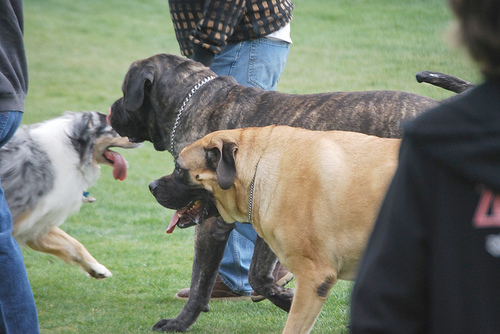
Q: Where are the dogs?
A: At the park.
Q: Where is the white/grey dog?
A: Left Side.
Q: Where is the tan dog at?
A: Right side.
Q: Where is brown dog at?
A: Between other dogs.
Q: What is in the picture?
A: Three dogs.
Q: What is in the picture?
A: Three people.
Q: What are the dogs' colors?
A: Brown, black, white and gray.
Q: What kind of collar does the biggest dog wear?
A: Silver chain collar.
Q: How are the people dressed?
A: For chilly weather.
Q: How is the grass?
A: Well manicured and green.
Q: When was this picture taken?
A: Maybe the afternoon.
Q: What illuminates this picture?
A: Natural sunlight.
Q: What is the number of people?
A: Three.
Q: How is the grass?
A: Well manicured green lawn.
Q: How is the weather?
A: Sunny.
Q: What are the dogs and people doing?
A: Walking and playing.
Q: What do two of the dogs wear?
A: Silver chain collars.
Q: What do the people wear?
A: Long sleeves and long pants.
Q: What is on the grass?
A: Dogs.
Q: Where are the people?
A: On the grass.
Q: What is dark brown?
A: The dog.